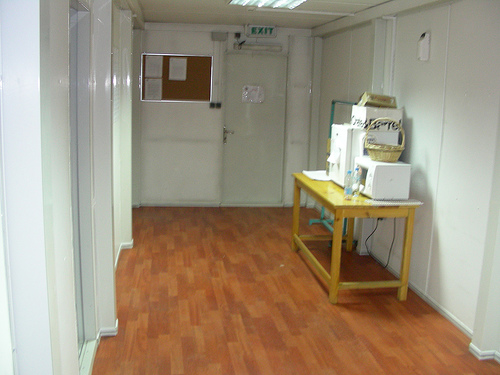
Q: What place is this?
A: It is a hallway.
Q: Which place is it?
A: It is a hallway.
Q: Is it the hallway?
A: Yes, it is the hallway.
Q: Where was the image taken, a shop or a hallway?
A: It was taken at a hallway.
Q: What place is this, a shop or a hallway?
A: It is a hallway.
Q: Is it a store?
A: No, it is a hallway.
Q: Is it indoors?
A: Yes, it is indoors.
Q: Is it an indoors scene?
A: Yes, it is indoors.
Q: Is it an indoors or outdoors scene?
A: It is indoors.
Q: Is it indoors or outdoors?
A: It is indoors.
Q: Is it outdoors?
A: No, it is indoors.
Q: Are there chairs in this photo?
A: No, there are no chairs.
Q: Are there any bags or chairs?
A: No, there are no chairs or bags.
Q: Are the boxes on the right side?
A: Yes, the boxes are on the right of the image.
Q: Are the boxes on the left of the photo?
A: No, the boxes are on the right of the image.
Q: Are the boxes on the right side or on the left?
A: The boxes are on the right of the image.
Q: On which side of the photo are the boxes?
A: The boxes are on the right of the image.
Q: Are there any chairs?
A: No, there are no chairs.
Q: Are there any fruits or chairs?
A: No, there are no chairs or fruits.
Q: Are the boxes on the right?
A: Yes, the boxes are on the right of the image.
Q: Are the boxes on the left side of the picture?
A: No, the boxes are on the right of the image.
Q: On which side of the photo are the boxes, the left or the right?
A: The boxes are on the right of the image.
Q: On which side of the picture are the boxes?
A: The boxes are on the right of the image.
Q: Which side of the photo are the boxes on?
A: The boxes are on the right of the image.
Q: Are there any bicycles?
A: No, there are no bicycles.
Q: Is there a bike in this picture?
A: No, there are no bikes.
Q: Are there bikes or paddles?
A: No, there are no bikes or paddles.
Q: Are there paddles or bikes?
A: No, there are no bikes or paddles.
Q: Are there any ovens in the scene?
A: Yes, there is an oven.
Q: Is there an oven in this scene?
A: Yes, there is an oven.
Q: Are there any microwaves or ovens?
A: Yes, there is an oven.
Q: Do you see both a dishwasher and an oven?
A: No, there is an oven but no dishwashers.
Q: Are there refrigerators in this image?
A: No, there are no refrigerators.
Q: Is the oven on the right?
A: Yes, the oven is on the right of the image.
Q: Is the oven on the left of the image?
A: No, the oven is on the right of the image.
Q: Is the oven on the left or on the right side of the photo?
A: The oven is on the right of the image.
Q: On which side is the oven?
A: The oven is on the right of the image.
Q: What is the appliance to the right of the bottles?
A: The appliance is an oven.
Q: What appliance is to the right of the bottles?
A: The appliance is an oven.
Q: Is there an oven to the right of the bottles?
A: Yes, there is an oven to the right of the bottles.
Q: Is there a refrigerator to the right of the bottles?
A: No, there is an oven to the right of the bottles.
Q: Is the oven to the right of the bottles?
A: Yes, the oven is to the right of the bottles.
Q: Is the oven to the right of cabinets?
A: No, the oven is to the right of the bottles.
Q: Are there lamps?
A: No, there are no lamps.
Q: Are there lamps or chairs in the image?
A: No, there are no lamps or chairs.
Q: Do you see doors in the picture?
A: Yes, there is a door.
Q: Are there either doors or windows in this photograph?
A: Yes, there is a door.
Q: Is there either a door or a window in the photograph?
A: Yes, there is a door.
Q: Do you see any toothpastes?
A: No, there are no toothpastes.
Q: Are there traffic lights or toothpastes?
A: No, there are no toothpastes or traffic lights.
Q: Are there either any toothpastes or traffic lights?
A: No, there are no toothpastes or traffic lights.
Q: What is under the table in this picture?
A: The cord is under the table.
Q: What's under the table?
A: The cord is under the table.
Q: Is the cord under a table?
A: Yes, the cord is under a table.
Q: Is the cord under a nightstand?
A: No, the cord is under a table.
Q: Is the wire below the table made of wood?
A: Yes, the wire is below the table.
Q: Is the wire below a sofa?
A: No, the wire is below the table.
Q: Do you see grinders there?
A: No, there are no grinders.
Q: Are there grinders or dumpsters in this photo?
A: No, there are no grinders or dumpsters.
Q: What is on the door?
A: The paper is on the door.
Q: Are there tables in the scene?
A: Yes, there is a table.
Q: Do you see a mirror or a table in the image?
A: Yes, there is a table.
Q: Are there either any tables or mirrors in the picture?
A: Yes, there is a table.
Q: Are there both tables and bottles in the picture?
A: Yes, there are both a table and a bottle.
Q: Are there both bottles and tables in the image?
A: Yes, there are both a table and a bottle.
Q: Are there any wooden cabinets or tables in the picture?
A: Yes, there is a wood table.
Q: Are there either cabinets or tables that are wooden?
A: Yes, the table is wooden.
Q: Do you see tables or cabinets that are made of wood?
A: Yes, the table is made of wood.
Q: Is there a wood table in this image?
A: Yes, there is a wood table.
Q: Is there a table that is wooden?
A: Yes, there is a table that is wooden.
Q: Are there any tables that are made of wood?
A: Yes, there is a table that is made of wood.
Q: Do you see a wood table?
A: Yes, there is a table that is made of wood.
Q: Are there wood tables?
A: Yes, there is a table that is made of wood.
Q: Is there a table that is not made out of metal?
A: Yes, there is a table that is made of wood.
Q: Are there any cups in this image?
A: No, there are no cups.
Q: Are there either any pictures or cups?
A: No, there are no cups or pictures.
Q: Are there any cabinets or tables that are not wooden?
A: No, there is a table but it is wooden.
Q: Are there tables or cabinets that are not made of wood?
A: No, there is a table but it is made of wood.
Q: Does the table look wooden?
A: Yes, the table is wooden.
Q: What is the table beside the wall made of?
A: The table is made of wood.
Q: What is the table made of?
A: The table is made of wood.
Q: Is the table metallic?
A: No, the table is wooden.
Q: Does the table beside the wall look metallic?
A: No, the table is wooden.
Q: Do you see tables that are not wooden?
A: No, there is a table but it is wooden.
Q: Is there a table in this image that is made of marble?
A: No, there is a table but it is made of wood.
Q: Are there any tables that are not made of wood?
A: No, there is a table but it is made of wood.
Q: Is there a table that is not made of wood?
A: No, there is a table but it is made of wood.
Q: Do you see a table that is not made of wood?
A: No, there is a table but it is made of wood.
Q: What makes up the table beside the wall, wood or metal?
A: The table is made of wood.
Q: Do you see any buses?
A: No, there are no buses.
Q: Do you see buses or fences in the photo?
A: No, there are no buses or fences.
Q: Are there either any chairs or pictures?
A: No, there are no chairs or pictures.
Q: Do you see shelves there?
A: No, there are no shelves.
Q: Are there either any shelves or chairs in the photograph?
A: No, there are no shelves or chairs.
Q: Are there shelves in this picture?
A: No, there are no shelves.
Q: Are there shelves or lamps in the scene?
A: No, there are no shelves or lamps.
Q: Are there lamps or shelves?
A: No, there are no shelves or lamps.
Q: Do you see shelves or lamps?
A: No, there are no shelves or lamps.